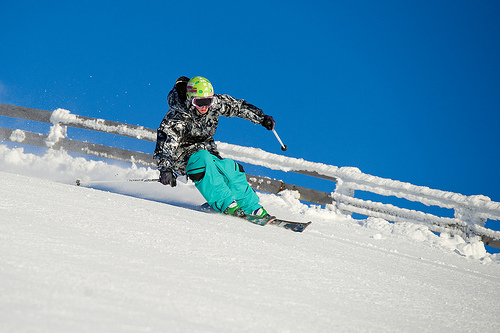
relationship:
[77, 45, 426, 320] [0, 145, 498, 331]
person on snow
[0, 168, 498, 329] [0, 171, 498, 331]
ground covered in white snow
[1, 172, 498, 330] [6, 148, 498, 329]
snow covering ground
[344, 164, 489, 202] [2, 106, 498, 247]
snow on railings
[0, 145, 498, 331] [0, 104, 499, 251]
snow on fence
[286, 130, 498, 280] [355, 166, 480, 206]
fence with snow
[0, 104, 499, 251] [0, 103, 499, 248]
fence with snow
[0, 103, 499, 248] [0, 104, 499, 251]
snow sitting on fence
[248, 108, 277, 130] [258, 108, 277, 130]
glove on hand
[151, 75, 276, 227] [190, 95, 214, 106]
person wearing goggles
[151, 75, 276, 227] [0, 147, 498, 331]
person down ground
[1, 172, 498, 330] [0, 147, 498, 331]
snow covering ground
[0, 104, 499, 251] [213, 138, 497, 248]
fence covered in snow